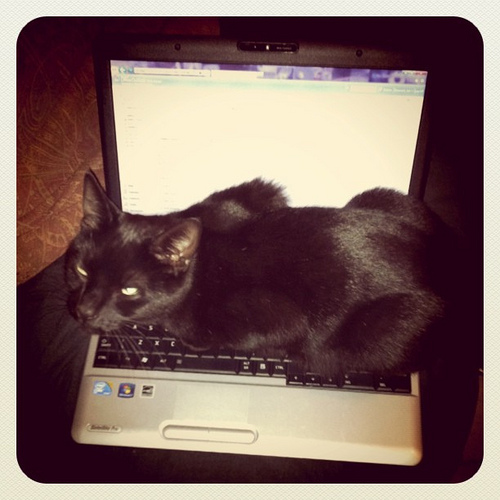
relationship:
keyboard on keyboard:
[92, 323, 410, 393] [86, 316, 422, 403]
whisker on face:
[105, 318, 179, 369] [61, 167, 195, 337]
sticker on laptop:
[93, 380, 112, 397] [67, 30, 448, 468]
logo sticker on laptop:
[117, 382, 135, 398] [67, 30, 448, 468]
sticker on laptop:
[139, 381, 156, 398] [67, 30, 448, 468]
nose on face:
[78, 301, 95, 322] [64, 222, 176, 342]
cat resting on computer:
[39, 166, 475, 379] [46, 31, 447, 472]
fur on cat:
[60, 162, 480, 382] [60, 165, 480, 382]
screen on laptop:
[110, 58, 428, 215] [67, 30, 448, 468]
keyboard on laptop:
[92, 323, 410, 393] [67, 30, 448, 468]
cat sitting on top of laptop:
[60, 165, 480, 382] [67, 30, 448, 468]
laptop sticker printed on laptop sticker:
[86, 423, 120, 433] [85, 421, 120, 432]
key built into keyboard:
[89, 349, 123, 369] [91, 319, 412, 396]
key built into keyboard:
[93, 332, 125, 352] [91, 319, 412, 396]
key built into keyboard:
[115, 350, 138, 370] [91, 319, 412, 396]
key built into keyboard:
[134, 351, 154, 370] [91, 319, 412, 396]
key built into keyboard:
[150, 350, 174, 370] [91, 319, 412, 396]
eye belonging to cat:
[75, 263, 88, 277] [60, 165, 480, 382]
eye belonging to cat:
[116, 284, 139, 295] [60, 165, 480, 382]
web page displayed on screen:
[110, 66, 423, 215] [110, 58, 428, 215]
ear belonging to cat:
[144, 213, 204, 275] [60, 165, 480, 382]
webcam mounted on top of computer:
[233, 37, 302, 53] [46, 31, 447, 472]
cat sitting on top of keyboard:
[60, 165, 480, 382] [91, 319, 412, 396]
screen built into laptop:
[110, 58, 428, 215] [67, 30, 448, 468]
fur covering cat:
[60, 162, 480, 382] [60, 165, 480, 382]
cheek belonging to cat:
[94, 294, 154, 332] [60, 165, 480, 382]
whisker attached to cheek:
[105, 318, 179, 369] [94, 294, 154, 332]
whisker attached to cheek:
[119, 328, 150, 377] [94, 294, 154, 332]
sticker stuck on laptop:
[89, 378, 113, 398] [67, 30, 448, 468]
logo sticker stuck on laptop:
[117, 382, 135, 398] [67, 30, 448, 468]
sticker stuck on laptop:
[139, 381, 156, 398] [67, 30, 448, 468]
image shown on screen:
[111, 58, 428, 86] [110, 58, 428, 215]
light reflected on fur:
[330, 202, 409, 294] [60, 162, 480, 382]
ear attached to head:
[76, 165, 124, 232] [59, 210, 197, 338]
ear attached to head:
[144, 213, 204, 275] [59, 210, 197, 338]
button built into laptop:
[161, 423, 255, 444] [67, 30, 448, 468]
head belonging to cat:
[59, 210, 197, 338] [60, 165, 480, 382]